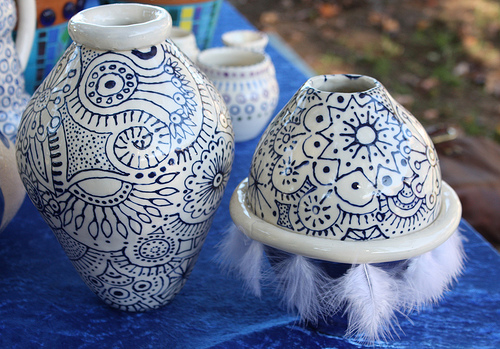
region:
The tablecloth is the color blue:
[3, 308, 296, 347]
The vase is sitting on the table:
[11, 8, 235, 317]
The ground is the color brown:
[328, 13, 489, 75]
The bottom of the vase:
[212, 213, 486, 345]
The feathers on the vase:
[218, 238, 463, 313]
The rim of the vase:
[56, 5, 177, 50]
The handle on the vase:
[8, 0, 53, 75]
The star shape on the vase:
[303, 98, 408, 198]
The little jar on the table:
[189, 37, 279, 147]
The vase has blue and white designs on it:
[54, 84, 191, 274]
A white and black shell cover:
[252, 103, 467, 345]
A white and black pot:
[57, 14, 216, 338]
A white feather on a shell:
[340, 259, 394, 332]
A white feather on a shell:
[284, 255, 320, 319]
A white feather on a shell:
[409, 251, 437, 308]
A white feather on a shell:
[244, 238, 265, 301]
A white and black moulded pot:
[200, 39, 272, 126]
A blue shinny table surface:
[20, 282, 90, 346]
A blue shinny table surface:
[190, 280, 241, 345]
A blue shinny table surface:
[440, 297, 498, 347]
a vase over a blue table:
[7, 0, 245, 329]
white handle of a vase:
[0, 0, 45, 92]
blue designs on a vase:
[7, 7, 239, 320]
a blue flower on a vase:
[162, 114, 232, 226]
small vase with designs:
[223, 66, 473, 331]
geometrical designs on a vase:
[249, 94, 448, 259]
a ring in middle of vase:
[228, 173, 467, 263]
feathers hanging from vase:
[206, 212, 471, 337]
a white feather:
[331, 263, 403, 342]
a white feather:
[398, 249, 449, 314]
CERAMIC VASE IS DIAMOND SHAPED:
[7, 5, 219, 297]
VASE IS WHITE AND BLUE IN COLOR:
[41, 13, 213, 313]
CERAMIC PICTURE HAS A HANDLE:
[3, 0, 37, 226]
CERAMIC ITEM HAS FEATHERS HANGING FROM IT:
[220, 208, 471, 313]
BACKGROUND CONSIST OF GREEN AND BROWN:
[322, 14, 490, 144]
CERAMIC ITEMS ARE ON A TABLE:
[1, 5, 469, 318]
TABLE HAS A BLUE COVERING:
[5, 158, 490, 335]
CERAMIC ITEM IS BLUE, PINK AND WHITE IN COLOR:
[199, 49, 292, 149]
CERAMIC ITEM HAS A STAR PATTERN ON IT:
[241, 73, 461, 280]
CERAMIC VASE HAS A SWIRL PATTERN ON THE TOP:
[57, 65, 171, 166]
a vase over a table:
[15, 9, 235, 324]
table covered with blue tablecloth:
[4, 5, 496, 347]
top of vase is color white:
[60, 2, 182, 69]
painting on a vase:
[12, 0, 233, 318]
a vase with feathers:
[225, 62, 472, 336]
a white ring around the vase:
[221, 169, 479, 263]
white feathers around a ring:
[215, 208, 469, 339]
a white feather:
[348, 262, 403, 340]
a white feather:
[278, 258, 326, 326]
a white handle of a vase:
[1, 0, 39, 212]